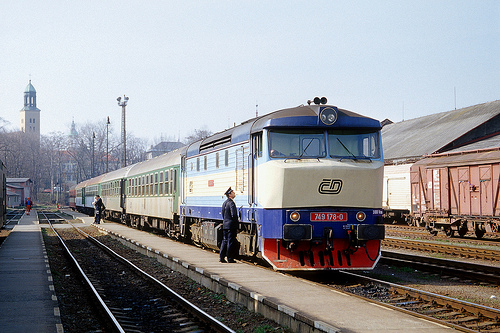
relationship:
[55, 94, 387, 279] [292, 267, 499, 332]
train on tracks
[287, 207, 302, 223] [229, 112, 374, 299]
headlight of train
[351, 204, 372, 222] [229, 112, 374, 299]
headlight of train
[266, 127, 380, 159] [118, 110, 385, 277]
windows of train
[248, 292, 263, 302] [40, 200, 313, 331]
white stripes are on side of track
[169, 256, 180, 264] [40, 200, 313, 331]
white stripes are on side of track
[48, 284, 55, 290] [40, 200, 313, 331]
white stripes are on side of track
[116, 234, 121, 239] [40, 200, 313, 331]
white stripes are on side of track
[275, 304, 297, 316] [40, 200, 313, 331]
white stripes are on side of track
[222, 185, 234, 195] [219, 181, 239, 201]
cap on head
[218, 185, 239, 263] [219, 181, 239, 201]
man has head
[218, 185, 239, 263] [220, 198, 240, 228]
man wearing jacket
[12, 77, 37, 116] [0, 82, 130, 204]
dome on top of building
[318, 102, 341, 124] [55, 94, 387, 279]
light on train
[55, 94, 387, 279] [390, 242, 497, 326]
train are on tracks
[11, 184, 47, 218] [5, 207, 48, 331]
person walking on sidewalk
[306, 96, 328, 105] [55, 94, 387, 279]
horns are on top of train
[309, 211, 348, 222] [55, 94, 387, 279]
tag on train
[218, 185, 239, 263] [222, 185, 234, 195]
man wearing cap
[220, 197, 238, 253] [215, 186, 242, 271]
clothes of man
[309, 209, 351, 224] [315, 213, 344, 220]
tag has lettering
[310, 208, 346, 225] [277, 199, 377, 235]
lettering on sign